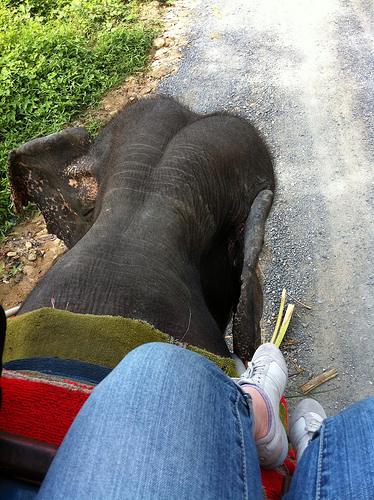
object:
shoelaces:
[238, 362, 264, 381]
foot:
[239, 342, 288, 471]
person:
[34, 343, 373, 499]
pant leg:
[36, 341, 262, 499]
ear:
[7, 126, 96, 251]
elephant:
[0, 96, 295, 498]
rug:
[0, 307, 295, 500]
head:
[95, 96, 276, 264]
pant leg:
[284, 395, 373, 499]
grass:
[0, 68, 18, 91]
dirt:
[2, 0, 187, 317]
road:
[151, 1, 373, 424]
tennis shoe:
[236, 342, 288, 470]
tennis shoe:
[289, 398, 329, 463]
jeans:
[35, 343, 373, 499]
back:
[14, 248, 231, 357]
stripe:
[0, 371, 94, 448]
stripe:
[2, 307, 241, 378]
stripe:
[1, 358, 112, 385]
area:
[9, 126, 103, 249]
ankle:
[241, 384, 270, 442]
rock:
[152, 38, 164, 47]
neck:
[45, 183, 219, 270]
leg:
[34, 342, 270, 499]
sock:
[241, 383, 273, 433]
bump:
[112, 96, 176, 152]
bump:
[185, 113, 269, 174]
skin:
[7, 95, 277, 369]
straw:
[269, 287, 294, 346]